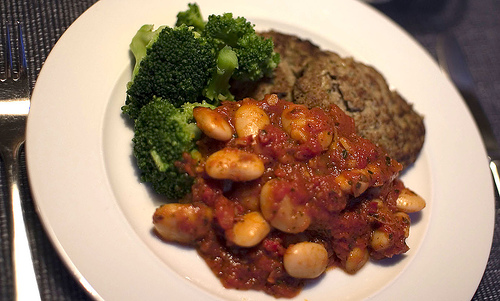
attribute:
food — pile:
[117, 17, 429, 279]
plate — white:
[22, 1, 482, 299]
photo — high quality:
[2, 0, 484, 297]